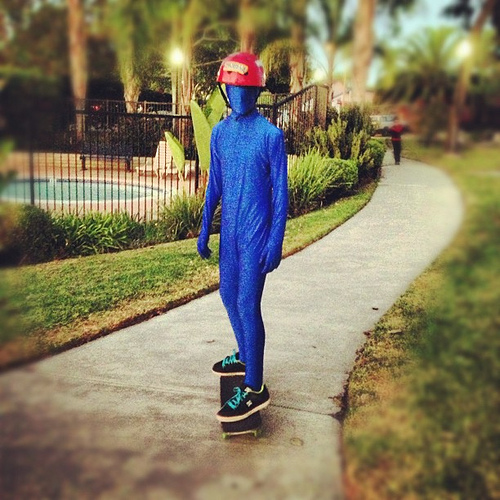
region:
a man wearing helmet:
[201, 44, 381, 278]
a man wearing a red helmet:
[155, 36, 332, 125]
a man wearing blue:
[155, 75, 417, 490]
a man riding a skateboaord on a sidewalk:
[123, 53, 390, 499]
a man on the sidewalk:
[115, 80, 335, 487]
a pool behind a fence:
[9, 151, 185, 221]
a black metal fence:
[83, 84, 395, 312]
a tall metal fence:
[29, 97, 390, 282]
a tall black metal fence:
[29, 44, 290, 222]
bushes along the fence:
[83, 182, 267, 251]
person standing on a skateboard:
[180, 43, 321, 452]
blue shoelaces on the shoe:
[213, 380, 282, 427]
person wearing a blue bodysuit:
[182, 40, 307, 407]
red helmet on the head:
[208, 42, 279, 127]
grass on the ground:
[342, 118, 498, 499]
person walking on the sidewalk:
[382, 110, 417, 170]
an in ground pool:
[1, 163, 172, 207]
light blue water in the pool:
[6, 172, 165, 203]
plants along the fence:
[1, 79, 377, 275]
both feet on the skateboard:
[204, 344, 284, 434]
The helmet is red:
[202, 34, 286, 116]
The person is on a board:
[174, 344, 306, 469]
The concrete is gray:
[72, 349, 196, 446]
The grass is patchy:
[398, 332, 498, 479]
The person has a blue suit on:
[138, 95, 307, 387]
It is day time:
[294, 9, 491, 103]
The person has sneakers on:
[199, 378, 316, 465]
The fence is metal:
[94, 69, 249, 265]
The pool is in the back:
[46, 155, 193, 258]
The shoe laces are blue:
[207, 377, 256, 414]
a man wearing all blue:
[183, 32, 354, 470]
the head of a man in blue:
[204, 47, 270, 117]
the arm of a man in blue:
[184, 143, 227, 263]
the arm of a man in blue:
[258, 130, 293, 280]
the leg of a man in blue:
[232, 268, 274, 385]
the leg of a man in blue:
[214, 255, 241, 360]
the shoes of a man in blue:
[205, 343, 272, 428]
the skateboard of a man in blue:
[203, 347, 270, 448]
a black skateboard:
[211, 350, 266, 441]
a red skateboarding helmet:
[210, 46, 274, 90]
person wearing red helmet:
[202, 50, 259, 104]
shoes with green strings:
[206, 372, 313, 454]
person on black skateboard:
[209, 351, 274, 456]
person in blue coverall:
[218, 225, 287, 285]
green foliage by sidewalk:
[417, 340, 447, 380]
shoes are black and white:
[217, 380, 238, 408]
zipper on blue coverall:
[222, 223, 263, 254]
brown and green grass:
[97, 316, 119, 323]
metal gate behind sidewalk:
[113, 213, 160, 223]